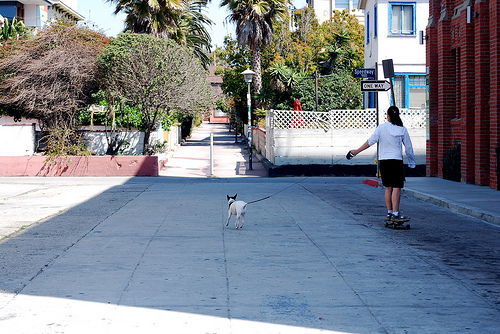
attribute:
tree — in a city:
[105, 30, 217, 151]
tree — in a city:
[301, 8, 363, 80]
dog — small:
[226, 192, 248, 228]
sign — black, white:
[354, 76, 390, 96]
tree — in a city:
[209, 22, 262, 142]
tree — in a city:
[260, 26, 320, 108]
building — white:
[363, 0, 430, 109]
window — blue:
[391, 2, 413, 34]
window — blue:
[394, 76, 404, 108]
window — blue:
[408, 74, 427, 85]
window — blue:
[407, 84, 430, 109]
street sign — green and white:
[354, 58, 392, 93]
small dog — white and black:
[205, 187, 276, 237]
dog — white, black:
[217, 190, 252, 234]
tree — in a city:
[302, 33, 354, 121]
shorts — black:
[378, 157, 405, 187]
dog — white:
[212, 188, 277, 248]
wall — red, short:
[0, 152, 160, 178]